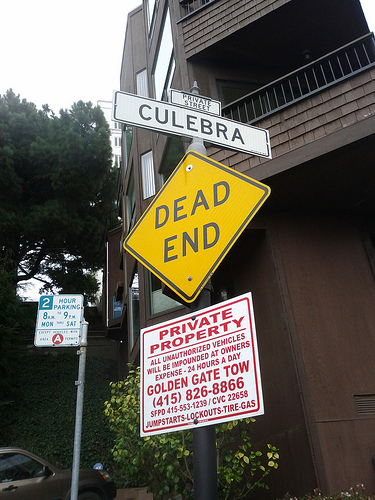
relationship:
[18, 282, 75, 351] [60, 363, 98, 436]
sign on post